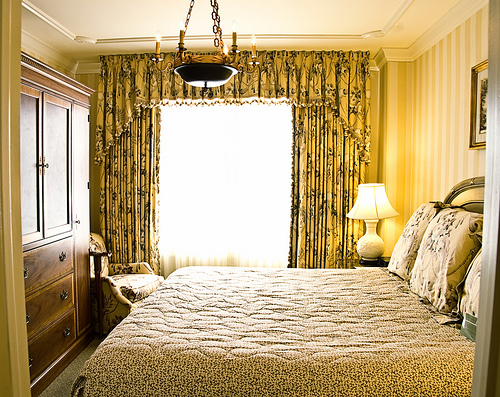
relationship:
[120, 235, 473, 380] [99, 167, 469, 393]
comfertor on bed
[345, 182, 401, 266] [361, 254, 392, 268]
lamp on stand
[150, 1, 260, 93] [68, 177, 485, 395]
lamp above bed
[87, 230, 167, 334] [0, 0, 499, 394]
chair in corner of room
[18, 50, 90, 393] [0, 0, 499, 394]
chest in room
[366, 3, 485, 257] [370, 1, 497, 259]
wall paper on wall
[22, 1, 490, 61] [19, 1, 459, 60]
crown molding on ceiling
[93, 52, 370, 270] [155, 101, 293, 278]
curtains on window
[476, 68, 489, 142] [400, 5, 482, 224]
picture on wall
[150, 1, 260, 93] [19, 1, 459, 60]
lamp on ceiling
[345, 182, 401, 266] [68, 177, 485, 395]
lamp by bed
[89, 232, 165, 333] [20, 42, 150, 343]
chair by corner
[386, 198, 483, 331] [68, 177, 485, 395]
pillows on bed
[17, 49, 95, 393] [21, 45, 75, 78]
cabinet along wall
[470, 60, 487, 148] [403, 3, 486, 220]
picture on wall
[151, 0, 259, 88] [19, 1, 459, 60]
lamp on ceiling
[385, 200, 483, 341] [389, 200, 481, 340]
pillow cases on pillows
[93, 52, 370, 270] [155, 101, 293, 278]
curtains by window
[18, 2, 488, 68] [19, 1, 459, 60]
molding on ceiling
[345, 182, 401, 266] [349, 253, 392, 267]
lamp on table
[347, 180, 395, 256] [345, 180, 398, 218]
lamp with lamp shade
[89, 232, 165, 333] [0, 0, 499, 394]
chair in corner room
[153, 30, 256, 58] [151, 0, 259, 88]
lights on lamp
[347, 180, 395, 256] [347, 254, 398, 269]
lamp sitting on stand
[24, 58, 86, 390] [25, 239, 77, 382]
chest have drawers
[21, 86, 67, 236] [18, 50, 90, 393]
door on chest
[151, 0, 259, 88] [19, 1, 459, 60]
lamp hanging from ceiling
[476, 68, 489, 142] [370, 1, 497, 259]
picture on wall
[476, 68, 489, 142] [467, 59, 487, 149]
picture with frame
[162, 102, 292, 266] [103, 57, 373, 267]
curtains on window